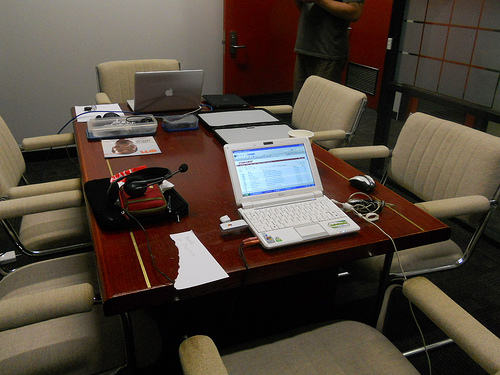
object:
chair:
[330, 109, 499, 282]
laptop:
[223, 136, 361, 252]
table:
[67, 95, 452, 318]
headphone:
[104, 162, 193, 203]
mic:
[175, 163, 187, 174]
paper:
[166, 230, 229, 290]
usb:
[215, 219, 247, 230]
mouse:
[346, 172, 375, 192]